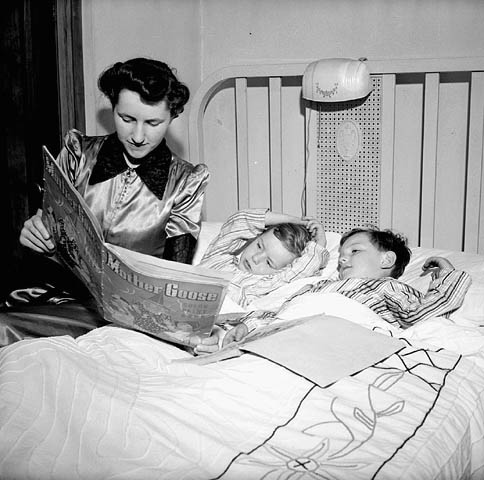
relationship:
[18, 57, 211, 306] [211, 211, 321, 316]
woman reading to shirt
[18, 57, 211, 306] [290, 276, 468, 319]
woman reading to shirt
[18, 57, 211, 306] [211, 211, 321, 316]
mother with shirt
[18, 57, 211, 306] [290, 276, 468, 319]
mother with shirt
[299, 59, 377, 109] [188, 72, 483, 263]
lamp on bed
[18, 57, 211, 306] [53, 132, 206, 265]
woman in dress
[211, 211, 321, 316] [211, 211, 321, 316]
shirt in shirt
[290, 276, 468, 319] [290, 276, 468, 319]
shirt in shirt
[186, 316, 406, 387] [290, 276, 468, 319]
book across shirt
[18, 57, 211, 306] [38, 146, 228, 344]
woman reading book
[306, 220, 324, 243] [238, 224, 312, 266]
hand above head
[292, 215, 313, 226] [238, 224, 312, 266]
hand above head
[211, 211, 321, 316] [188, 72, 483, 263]
shirt in bed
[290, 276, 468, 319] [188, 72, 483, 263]
shirt in bed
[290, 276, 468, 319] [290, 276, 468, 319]
shirt wearing pajama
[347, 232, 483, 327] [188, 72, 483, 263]
pillow on bed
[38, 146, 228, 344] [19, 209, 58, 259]
book in hand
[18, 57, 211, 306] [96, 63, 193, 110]
woman has hair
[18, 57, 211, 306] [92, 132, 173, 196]
woman has collar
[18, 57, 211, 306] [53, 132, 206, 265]
woman has blouse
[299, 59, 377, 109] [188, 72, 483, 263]
light above bed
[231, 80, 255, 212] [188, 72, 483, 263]
rail on bed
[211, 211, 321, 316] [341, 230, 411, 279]
shirt has hair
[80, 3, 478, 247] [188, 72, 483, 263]
wall behind bed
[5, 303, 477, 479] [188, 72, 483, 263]
blanket on bed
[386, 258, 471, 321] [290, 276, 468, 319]
arm on shirt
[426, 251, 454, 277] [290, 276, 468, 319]
hand on shirt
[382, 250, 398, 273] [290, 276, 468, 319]
ear on shirt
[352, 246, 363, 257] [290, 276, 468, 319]
eye on shirt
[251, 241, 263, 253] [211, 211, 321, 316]
eye on shirt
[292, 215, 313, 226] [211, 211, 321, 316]
hand on shirt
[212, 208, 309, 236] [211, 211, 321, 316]
arm on shirt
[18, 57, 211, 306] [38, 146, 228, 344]
woman holds book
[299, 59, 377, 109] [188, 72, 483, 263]
lamp on headboard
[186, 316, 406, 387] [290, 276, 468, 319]
book on shirt